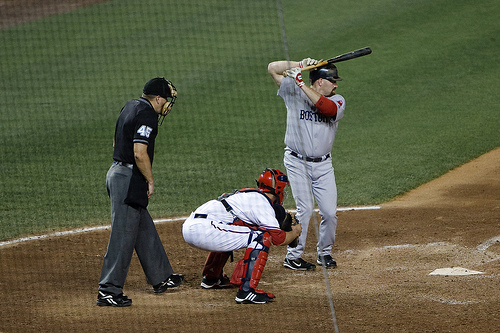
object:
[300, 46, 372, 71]
bat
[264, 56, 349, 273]
batter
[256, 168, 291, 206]
helmet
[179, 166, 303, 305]
catcher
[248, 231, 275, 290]
knee guard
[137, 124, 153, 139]
number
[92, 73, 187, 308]
umpire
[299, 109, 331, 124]
team name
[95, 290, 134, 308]
sneaker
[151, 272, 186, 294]
sneaker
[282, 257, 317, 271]
shoe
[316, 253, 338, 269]
shoe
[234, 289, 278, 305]
shoe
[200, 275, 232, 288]
shoe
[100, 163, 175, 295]
pants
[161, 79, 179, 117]
faceguard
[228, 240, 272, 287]
box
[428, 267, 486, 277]
plate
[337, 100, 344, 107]
logo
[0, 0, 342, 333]
net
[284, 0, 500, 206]
grass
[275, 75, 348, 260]
uniform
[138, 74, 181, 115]
head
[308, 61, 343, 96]
head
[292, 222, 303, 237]
hand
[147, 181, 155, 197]
hand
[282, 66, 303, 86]
hand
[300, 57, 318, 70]
hand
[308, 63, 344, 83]
helmet